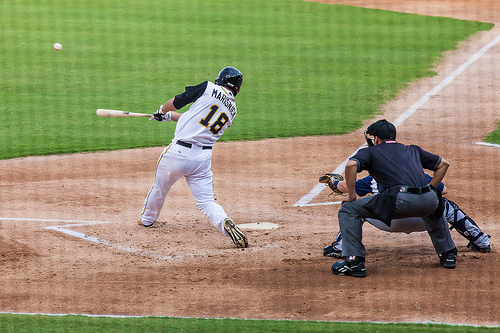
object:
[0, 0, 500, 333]
ground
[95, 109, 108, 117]
part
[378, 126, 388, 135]
part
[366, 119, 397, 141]
cap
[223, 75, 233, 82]
part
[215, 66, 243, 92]
helmet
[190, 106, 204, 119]
part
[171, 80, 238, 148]
top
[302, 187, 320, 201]
part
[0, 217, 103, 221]
line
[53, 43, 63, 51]
baseball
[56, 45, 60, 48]
part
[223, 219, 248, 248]
sole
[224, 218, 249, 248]
shoe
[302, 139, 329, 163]
part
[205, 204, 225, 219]
part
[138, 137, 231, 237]
trouser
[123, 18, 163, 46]
part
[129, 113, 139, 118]
part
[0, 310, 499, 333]
edge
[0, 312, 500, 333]
grass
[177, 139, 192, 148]
part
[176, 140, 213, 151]
belt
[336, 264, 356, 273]
part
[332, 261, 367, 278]
shoe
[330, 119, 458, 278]
umpire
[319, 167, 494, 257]
catcher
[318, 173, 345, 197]
glove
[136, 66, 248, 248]
player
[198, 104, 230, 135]
number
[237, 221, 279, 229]
plate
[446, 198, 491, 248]
shin guard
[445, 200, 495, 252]
leg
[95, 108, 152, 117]
bat